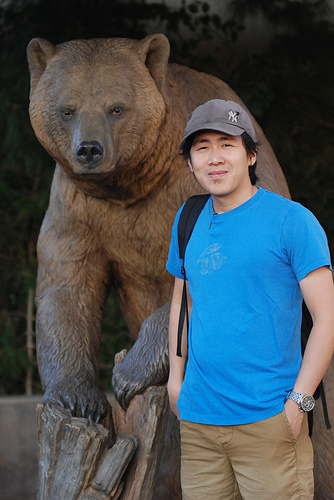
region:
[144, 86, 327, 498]
a man wearing blue shirt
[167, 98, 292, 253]
man is smiling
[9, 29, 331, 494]
a man is standing next to a wooden bear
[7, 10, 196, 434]
wooden bear is brown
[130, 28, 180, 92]
right ear of bear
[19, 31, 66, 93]
left ear of bear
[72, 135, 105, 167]
nostrils of right ear of bear are black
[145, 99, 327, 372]
man holds a backpack on right shoulder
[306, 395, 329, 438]
straps of backpack are black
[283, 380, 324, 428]
a clock on a wrist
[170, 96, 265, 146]
gray yankees hat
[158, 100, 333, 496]
man standing in front of bear statute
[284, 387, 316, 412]
watch on man's wrist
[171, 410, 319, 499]
beige pants of man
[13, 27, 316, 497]
brown bear statute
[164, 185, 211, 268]
strap of black backpack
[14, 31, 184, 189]
head of brown bear statute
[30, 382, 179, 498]
fake log base of brown bear statute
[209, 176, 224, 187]
patch of man's facial hair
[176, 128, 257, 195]
smiling face of man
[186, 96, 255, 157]
Man wearing gray hat.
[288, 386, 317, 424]
Silver watch around man's wrist.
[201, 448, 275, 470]
Man wearing tan pants.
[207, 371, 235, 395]
Man wearing blue shirt.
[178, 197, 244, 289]
Black strap around man's shoulder.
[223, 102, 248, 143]
NY on man's hat.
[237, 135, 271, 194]
Man has black hair.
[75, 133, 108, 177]
Bear has black nose.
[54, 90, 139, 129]
Bear has brown eyes.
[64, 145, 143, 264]
Bear has brown fur.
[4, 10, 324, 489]
man posing with statue of bear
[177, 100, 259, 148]
New York Yankees ball cap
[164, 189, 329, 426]
bright blue short-sleeved t-shirt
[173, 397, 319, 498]
khaki pants with front pockets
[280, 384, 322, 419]
silver watch on left wrist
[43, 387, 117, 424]
long bear claws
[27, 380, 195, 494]
statue of tree stump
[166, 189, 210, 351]
strap of backpack worn over right shoulder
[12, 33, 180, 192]
head of bear statue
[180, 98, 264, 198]
man with black hair smiling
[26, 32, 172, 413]
a museum display of a grizzly bear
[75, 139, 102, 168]
the black nose of a grizzly bear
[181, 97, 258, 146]
a grey baseball cap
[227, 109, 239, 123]
a grey NY logo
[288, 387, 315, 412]
a silver wrist watch on the mans left wrist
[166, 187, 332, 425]
the man is wearing a blue t-shirt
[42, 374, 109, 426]
the grizzly's large paws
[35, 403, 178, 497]
a display of a boken tree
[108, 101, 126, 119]
the grizzly's brown eye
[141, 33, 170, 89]
the grizzly's brown ear